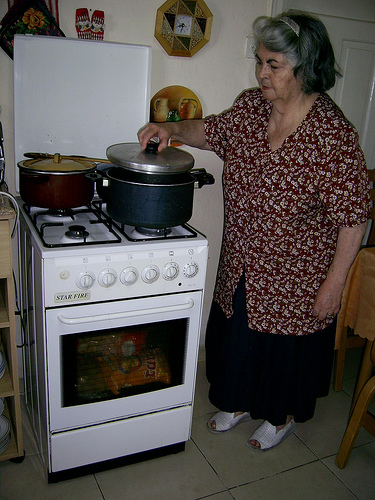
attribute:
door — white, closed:
[268, 1, 374, 246]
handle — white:
[57, 298, 202, 328]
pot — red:
[19, 152, 94, 206]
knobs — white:
[188, 252, 200, 285]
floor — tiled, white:
[1, 345, 374, 499]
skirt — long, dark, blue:
[194, 262, 345, 343]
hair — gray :
[253, 10, 314, 59]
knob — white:
[75, 272, 96, 291]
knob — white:
[99, 273, 119, 289]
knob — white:
[119, 264, 139, 283]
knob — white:
[141, 262, 160, 286]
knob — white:
[162, 262, 178, 280]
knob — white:
[182, 262, 199, 276]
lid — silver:
[106, 140, 193, 175]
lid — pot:
[106, 138, 195, 171]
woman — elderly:
[139, 11, 367, 447]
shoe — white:
[247, 412, 299, 454]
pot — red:
[16, 150, 100, 206]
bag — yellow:
[96, 346, 171, 394]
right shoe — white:
[209, 402, 247, 434]